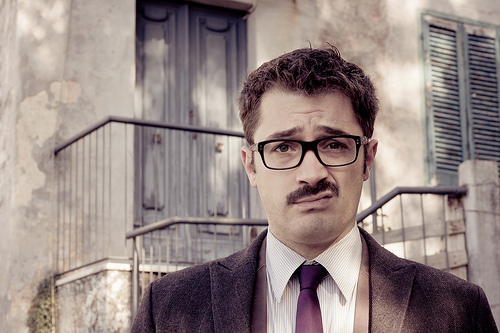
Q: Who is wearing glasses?
A: The man.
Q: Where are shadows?
A: On the building.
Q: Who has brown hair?
A: A man.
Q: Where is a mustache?
A: On man's face.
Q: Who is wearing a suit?
A: The man.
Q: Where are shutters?
A: On the building.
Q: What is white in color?
A: Man's shirt.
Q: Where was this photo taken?
A: Outside of a stone building.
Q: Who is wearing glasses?
A: The man with the purple tie.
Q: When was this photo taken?
A: During the daytime.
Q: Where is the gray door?
A: Behind the man.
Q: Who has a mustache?
A: The man wearing glasses.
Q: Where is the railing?
A: Behind the man.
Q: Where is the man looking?
A: Toward the camera.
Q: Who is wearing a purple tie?
A: The man with glasses.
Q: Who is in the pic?
A: A man.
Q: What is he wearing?
A: Glasses.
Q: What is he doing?
A: Sneering.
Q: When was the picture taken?
A: During the day.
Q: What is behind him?
A: A house.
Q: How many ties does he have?
A: 1.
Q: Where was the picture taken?
A: On the street.